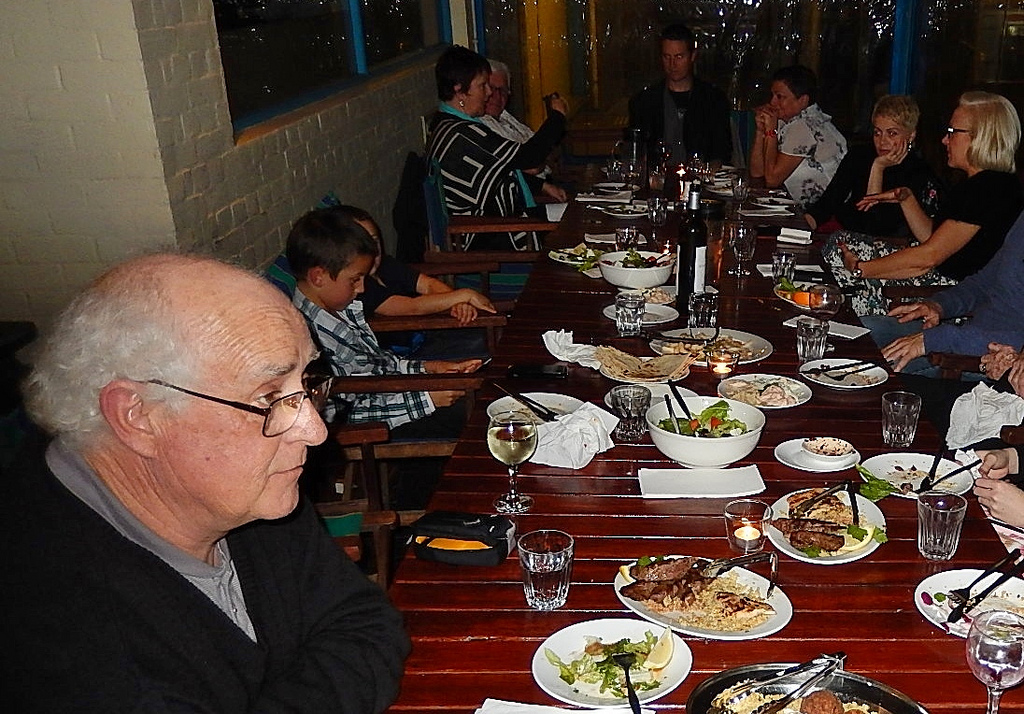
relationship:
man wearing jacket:
[8, 254, 417, 711] [0, 437, 418, 707]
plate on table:
[530, 615, 695, 709] [298, 143, 1017, 712]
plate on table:
[613, 556, 797, 643] [298, 143, 1017, 712]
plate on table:
[908, 571, 1023, 643] [298, 143, 1017, 712]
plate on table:
[759, 479, 906, 572] [298, 143, 1017, 712]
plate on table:
[857, 450, 976, 505] [298, 143, 1017, 712]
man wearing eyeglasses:
[8, 254, 417, 711] [144, 375, 335, 442]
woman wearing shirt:
[414, 40, 577, 254] [427, 105, 564, 248]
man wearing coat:
[596, 12, 753, 164] [625, 90, 753, 164]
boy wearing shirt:
[302, 215, 477, 427] [291, 305, 481, 435]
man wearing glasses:
[8, 254, 417, 711] [151, 363, 349, 428]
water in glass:
[518, 561, 568, 596] [523, 529, 584, 623]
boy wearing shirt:
[303, 215, 478, 427] [318, 303, 478, 427]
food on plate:
[760, 479, 866, 566] [760, 479, 906, 572]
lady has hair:
[882, 85, 1022, 279] [952, 87, 1022, 176]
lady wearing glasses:
[882, 85, 1022, 279] [948, 120, 1022, 150]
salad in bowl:
[664, 399, 747, 434] [651, 392, 756, 463]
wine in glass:
[477, 417, 538, 463] [477, 402, 554, 517]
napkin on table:
[641, 464, 765, 491] [298, 143, 1016, 712]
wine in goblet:
[477, 417, 538, 463] [487, 395, 541, 516]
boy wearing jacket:
[261, 207, 500, 435] [283, 290, 429, 426]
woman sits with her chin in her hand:
[822, 93, 939, 256] [885, 148, 914, 169]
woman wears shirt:
[855, 104, 1021, 339] [935, 154, 1002, 273]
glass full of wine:
[477, 402, 554, 517] [477, 417, 538, 463]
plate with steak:
[613, 556, 797, 643] [622, 544, 695, 601]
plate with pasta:
[613, 556, 797, 643] [664, 575, 781, 633]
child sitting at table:
[275, 209, 482, 447] [364, 96, 1019, 708]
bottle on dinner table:
[676, 187, 712, 311] [364, 96, 1019, 708]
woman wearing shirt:
[414, 40, 576, 254] [427, 105, 548, 260]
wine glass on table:
[477, 396, 542, 522] [298, 143, 1017, 712]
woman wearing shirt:
[855, 104, 1020, 339] [936, 154, 1004, 273]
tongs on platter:
[700, 646, 838, 710] [673, 637, 926, 710]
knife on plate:
[939, 572, 1022, 624] [917, 550, 1022, 658]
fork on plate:
[917, 553, 991, 592] [917, 550, 1022, 658]